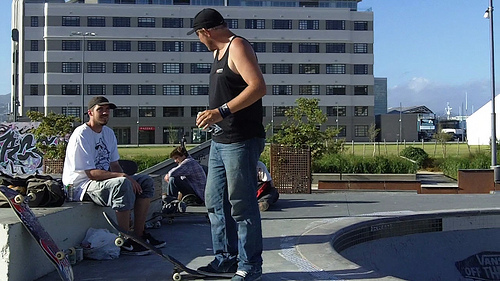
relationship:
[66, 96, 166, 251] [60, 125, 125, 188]
man wearing shirt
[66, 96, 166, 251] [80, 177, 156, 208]
man wearing shorts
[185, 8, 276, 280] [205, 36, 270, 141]
man wearing shirt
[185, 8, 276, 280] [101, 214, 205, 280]
man on top of skateboard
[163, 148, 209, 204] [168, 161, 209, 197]
man with shirt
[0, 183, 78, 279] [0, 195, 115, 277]
skateboard leaning on concrete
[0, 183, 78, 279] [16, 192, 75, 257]
skateboard with wheels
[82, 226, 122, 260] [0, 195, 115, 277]
bag against concrete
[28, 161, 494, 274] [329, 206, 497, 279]
concrete around park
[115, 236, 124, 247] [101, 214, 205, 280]
wheel on bottom of skateboard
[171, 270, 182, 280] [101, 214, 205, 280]
wheel on bottom of skateboard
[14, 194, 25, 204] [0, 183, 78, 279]
wheel on bottom of skateboard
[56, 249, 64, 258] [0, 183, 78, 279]
wheel on bottom of skateboard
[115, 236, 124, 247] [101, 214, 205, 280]
wheel of skateboard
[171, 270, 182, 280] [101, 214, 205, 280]
wheel of skateboard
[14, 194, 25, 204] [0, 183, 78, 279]
wheel of skateboard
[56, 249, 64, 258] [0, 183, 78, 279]
wheel of skateboard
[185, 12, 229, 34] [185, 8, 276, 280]
hat on head of man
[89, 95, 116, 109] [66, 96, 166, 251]
hat on head of man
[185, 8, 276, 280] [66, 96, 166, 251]
man looing at man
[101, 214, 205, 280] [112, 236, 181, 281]
skateboard with wheels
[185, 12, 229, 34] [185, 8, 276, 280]
hat on top of man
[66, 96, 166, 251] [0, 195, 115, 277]
man sitting on concrete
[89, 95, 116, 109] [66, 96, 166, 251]
hat on top of man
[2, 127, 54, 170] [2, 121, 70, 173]
graffiti on side of wall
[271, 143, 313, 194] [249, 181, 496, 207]
cage on top of sidewalk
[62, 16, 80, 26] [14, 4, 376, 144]
window on front of building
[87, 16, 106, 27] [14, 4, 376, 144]
window on front of building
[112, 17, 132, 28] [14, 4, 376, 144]
window on front of building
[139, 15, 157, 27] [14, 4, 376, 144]
window on front of building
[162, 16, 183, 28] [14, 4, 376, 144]
window on front of building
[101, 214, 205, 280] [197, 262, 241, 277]
skateboard under foot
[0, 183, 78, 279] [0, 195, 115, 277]
skateboard leaning against concrete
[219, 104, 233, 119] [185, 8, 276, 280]
band on wrist of man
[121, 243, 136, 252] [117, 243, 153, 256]
nike on side of nike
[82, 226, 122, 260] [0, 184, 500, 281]
bag sitting on concrete